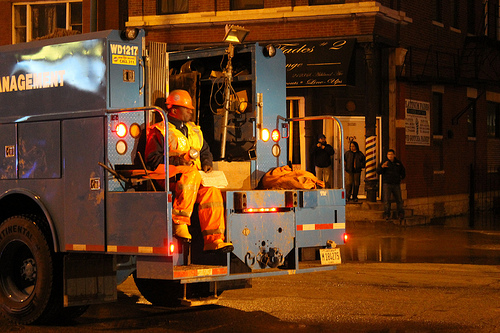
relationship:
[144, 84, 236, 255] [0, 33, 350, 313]
man sitting in back of truck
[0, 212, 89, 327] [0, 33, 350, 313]
tire on truck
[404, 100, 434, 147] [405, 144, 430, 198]
square sign on wall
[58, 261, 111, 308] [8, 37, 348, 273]
flap on truck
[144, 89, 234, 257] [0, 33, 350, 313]
man on truck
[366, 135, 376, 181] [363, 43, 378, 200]
stripes on pole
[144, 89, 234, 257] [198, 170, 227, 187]
man holds papers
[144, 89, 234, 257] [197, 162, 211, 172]
man has hand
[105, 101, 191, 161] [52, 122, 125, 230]
bar on truck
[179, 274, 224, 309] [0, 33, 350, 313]
step on truck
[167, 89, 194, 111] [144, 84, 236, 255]
hardhat on man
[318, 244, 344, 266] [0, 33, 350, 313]
license plate on truck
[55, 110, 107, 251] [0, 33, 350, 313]
compartments on truck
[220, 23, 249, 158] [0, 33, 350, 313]
portable light on truck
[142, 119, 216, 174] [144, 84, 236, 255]
shirt on man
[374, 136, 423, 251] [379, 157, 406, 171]
man wearing coat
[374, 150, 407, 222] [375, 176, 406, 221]
man wearing jeans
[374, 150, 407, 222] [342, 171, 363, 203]
man wearing jeans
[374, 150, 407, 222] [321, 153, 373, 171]
man wearing coat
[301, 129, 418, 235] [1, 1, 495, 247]
people standing by corner of building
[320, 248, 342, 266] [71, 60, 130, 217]
license plate on truck